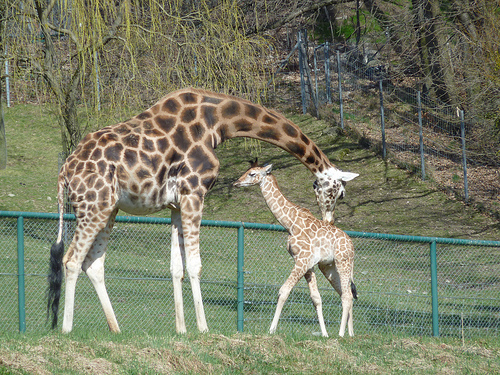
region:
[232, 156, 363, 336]
A baby giraffe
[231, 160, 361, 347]
A small giraffe standing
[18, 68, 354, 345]
An adult giraffe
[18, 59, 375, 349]
An adult giraffe and the baby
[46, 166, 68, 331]
The tail of the giraffe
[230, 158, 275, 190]
The head of the baby giraffe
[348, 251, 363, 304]
The tail of the small giraffe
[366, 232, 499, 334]
A green chain link fence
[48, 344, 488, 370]
A grassy field where animals live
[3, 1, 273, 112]
A large weeping willow tree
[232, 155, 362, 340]
a baby giraffe in the zoo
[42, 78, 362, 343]
a mama giraffe with her baby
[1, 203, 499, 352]
a fence contains the giraffes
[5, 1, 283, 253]
a tree behind the fence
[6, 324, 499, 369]
grass in the zoo enclosure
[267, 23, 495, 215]
a fence rises up the hillside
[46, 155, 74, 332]
the mama giraffe's long tail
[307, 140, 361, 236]
mama giraffes kisses her baby's back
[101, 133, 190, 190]
spots on the giraffe's back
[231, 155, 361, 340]
baby giraffe takes a step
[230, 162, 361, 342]
A small baby giraffe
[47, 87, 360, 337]
a tall large giraffe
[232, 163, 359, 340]
a baby giraffe with brown spots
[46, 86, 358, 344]
a giraffe with black spots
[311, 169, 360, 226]
a giraffe with black and white face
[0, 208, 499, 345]
a green metal fence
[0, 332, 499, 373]
green and brown grass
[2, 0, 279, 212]
a small tree with green leaves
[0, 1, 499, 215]
a large wooded area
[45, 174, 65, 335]
a giraffe with brown and black tail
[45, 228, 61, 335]
black tail of giraffe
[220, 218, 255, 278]
protective fence enclosure for the giraffes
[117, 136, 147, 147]
brown spot on the giraffe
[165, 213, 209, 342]
two legs on the giraffe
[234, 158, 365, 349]
baby giraffe near the momma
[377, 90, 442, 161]
metal fence beside the trees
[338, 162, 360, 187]
white ear of the giraffe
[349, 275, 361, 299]
tail of the baby giraffe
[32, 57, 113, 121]
green trees by the giraffe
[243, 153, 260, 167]
horns of the baby giraffe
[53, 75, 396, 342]
two giraffes beside the fence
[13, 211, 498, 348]
the fence is chain link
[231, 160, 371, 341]
the giraffe is young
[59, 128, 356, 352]
the giraffe grooming the other giraffe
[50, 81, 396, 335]
the giraffes are spotted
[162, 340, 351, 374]
hay in the grass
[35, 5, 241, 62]
weeping willow tree behind the fence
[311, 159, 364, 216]
the head of the giraffe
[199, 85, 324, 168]
the neck of the giraffe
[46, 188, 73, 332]
the tail of the giraffe